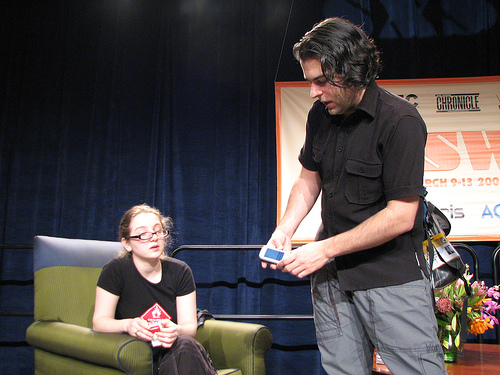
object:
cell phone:
[258, 246, 291, 265]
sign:
[262, 74, 497, 254]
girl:
[90, 200, 223, 375]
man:
[258, 13, 449, 375]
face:
[299, 52, 361, 117]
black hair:
[291, 17, 380, 90]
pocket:
[343, 157, 385, 206]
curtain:
[100, 37, 223, 193]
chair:
[25, 234, 275, 375]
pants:
[310, 259, 443, 375]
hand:
[276, 240, 331, 280]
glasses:
[126, 230, 168, 241]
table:
[372, 341, 497, 375]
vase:
[439, 324, 460, 364]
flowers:
[432, 263, 500, 364]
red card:
[139, 303, 172, 336]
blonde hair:
[116, 203, 179, 261]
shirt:
[297, 78, 432, 293]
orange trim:
[270, 74, 500, 243]